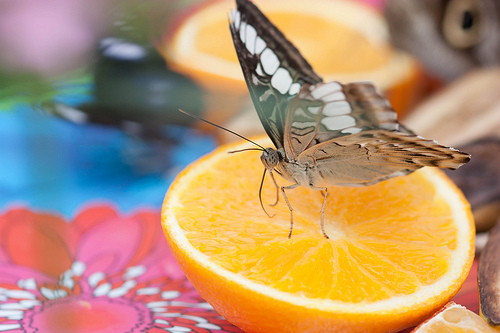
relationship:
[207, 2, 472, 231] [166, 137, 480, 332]
butterfly on orange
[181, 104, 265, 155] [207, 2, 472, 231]
antennae of butterfly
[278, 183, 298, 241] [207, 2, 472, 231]
leg of butterfly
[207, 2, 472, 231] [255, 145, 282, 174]
butterfly has head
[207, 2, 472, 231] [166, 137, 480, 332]
butterfly eating orange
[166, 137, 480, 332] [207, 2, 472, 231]
orange with butterfly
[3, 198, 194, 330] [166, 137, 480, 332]
flower under orange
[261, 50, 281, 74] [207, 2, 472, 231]
spot on butterfly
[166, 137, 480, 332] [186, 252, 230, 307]
orange has peel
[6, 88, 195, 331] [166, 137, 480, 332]
table cloth under orange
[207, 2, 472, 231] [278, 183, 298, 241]
butterfly has leg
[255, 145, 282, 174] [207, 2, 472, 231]
head of butterfly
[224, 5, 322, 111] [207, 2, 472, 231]
wing of butterfly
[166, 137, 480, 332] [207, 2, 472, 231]
orange under butterfly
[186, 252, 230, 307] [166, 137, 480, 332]
peel on orange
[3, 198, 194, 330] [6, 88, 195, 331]
flower on table cloth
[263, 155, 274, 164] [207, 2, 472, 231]
eye of butterfly